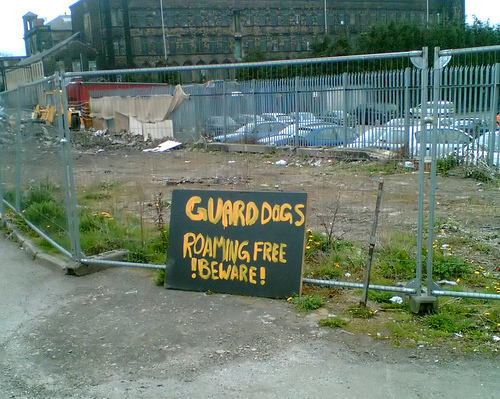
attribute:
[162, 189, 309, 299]
sign — green, hand written, black, yellow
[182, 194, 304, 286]
writing — yellow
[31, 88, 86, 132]
machine — yellow, heavy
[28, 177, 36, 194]
flower — white, growing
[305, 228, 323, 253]
flower — yellow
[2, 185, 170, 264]
grass — green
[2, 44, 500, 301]
fence — metal, tall, silver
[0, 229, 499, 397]
cement — gray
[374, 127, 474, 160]
car — gray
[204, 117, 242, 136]
car — black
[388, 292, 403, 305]
trash — grouped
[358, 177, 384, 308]
pole — metal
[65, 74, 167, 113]
building — red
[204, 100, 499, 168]
cars — parked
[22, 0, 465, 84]
building — large, in background, dark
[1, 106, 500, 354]
field — large